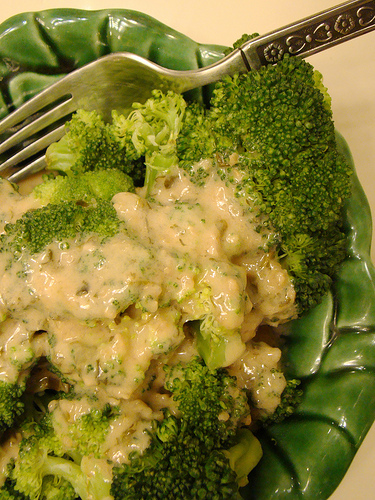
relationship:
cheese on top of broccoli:
[56, 237, 201, 324] [66, 115, 323, 357]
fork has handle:
[64, 8, 371, 107] [238, 19, 372, 68]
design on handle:
[290, 26, 374, 40] [238, 19, 372, 68]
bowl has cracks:
[5, 10, 225, 104] [41, 27, 77, 73]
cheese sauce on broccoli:
[49, 254, 233, 382] [66, 115, 323, 357]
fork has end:
[64, 8, 371, 107] [313, 22, 366, 56]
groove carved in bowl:
[4, 41, 130, 75] [5, 10, 225, 104]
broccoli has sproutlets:
[66, 115, 323, 357] [264, 105, 324, 191]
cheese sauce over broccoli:
[49, 254, 233, 382] [66, 115, 323, 357]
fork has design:
[64, 8, 371, 107] [290, 26, 374, 40]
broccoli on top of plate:
[66, 115, 323, 357] [28, 20, 374, 489]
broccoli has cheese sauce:
[66, 115, 323, 357] [49, 254, 233, 382]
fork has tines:
[64, 8, 371, 107] [261, 36, 370, 48]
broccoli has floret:
[66, 115, 323, 357] [257, 79, 315, 196]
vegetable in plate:
[58, 112, 308, 446] [28, 20, 374, 489]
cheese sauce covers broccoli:
[49, 254, 233, 382] [66, 115, 323, 357]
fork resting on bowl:
[64, 8, 371, 107] [5, 10, 225, 104]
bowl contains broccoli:
[5, 10, 225, 104] [66, 115, 323, 357]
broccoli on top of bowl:
[66, 115, 323, 357] [5, 10, 225, 104]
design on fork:
[290, 26, 374, 40] [64, 8, 371, 107]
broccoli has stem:
[66, 115, 323, 357] [137, 146, 183, 202]